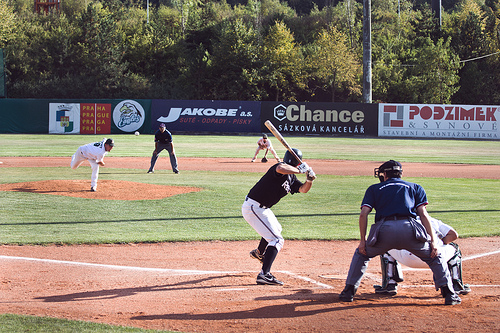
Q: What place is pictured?
A: It is a field.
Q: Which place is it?
A: It is a field.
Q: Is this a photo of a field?
A: Yes, it is showing a field.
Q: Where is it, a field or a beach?
A: It is a field.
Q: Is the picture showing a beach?
A: No, the picture is showing a field.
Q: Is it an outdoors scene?
A: Yes, it is outdoors.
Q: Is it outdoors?
A: Yes, it is outdoors.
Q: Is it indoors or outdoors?
A: It is outdoors.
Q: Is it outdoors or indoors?
A: It is outdoors.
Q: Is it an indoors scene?
A: No, it is outdoors.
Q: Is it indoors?
A: No, it is outdoors.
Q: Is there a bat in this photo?
A: Yes, there is a bat.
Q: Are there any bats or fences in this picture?
A: Yes, there is a bat.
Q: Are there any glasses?
A: No, there are no glasses.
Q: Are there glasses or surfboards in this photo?
A: No, there are no glasses or surfboards.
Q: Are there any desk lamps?
A: No, there are no desk lamps.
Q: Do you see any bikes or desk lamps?
A: No, there are no desk lamps or bikes.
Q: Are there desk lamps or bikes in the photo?
A: No, there are no desk lamps or bikes.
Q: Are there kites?
A: No, there are no kites.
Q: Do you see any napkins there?
A: No, there are no napkins.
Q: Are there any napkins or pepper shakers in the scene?
A: No, there are no napkins or pepper shakers.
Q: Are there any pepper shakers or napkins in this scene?
A: No, there are no napkins or pepper shakers.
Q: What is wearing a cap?
A: The pitcher is wearing a cap.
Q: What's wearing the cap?
A: The pitcher is wearing a cap.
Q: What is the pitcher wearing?
A: The pitcher is wearing a cap.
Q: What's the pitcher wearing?
A: The pitcher is wearing a cap.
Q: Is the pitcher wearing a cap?
A: Yes, the pitcher is wearing a cap.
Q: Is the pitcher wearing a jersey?
A: No, the pitcher is wearing a cap.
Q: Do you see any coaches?
A: No, there are no coaches.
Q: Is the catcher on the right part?
A: Yes, the catcher is on the right of the image.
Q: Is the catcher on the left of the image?
A: No, the catcher is on the right of the image.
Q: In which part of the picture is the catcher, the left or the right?
A: The catcher is on the right of the image.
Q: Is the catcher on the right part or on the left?
A: The catcher is on the right of the image.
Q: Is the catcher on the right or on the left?
A: The catcher is on the right of the image.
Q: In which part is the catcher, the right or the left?
A: The catcher is on the right of the image.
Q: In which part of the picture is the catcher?
A: The catcher is on the right of the image.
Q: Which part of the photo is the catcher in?
A: The catcher is on the right of the image.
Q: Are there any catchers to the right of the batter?
A: Yes, there is a catcher to the right of the batter.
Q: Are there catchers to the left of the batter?
A: No, the catcher is to the right of the batter.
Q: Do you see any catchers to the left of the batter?
A: No, the catcher is to the right of the batter.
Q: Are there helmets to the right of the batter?
A: No, there is a catcher to the right of the batter.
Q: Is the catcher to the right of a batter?
A: Yes, the catcher is to the right of a batter.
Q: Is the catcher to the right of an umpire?
A: No, the catcher is to the right of a batter.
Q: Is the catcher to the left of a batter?
A: No, the catcher is to the right of a batter.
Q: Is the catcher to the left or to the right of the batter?
A: The catcher is to the right of the batter.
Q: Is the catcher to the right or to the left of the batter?
A: The catcher is to the right of the batter.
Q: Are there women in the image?
A: No, there are no women.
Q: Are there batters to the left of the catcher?
A: Yes, there is a batter to the left of the catcher.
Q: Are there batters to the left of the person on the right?
A: Yes, there is a batter to the left of the catcher.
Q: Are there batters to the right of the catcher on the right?
A: No, the batter is to the left of the catcher.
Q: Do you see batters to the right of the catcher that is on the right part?
A: No, the batter is to the left of the catcher.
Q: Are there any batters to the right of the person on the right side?
A: No, the batter is to the left of the catcher.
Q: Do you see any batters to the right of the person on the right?
A: No, the batter is to the left of the catcher.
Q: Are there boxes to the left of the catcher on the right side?
A: No, there is a batter to the left of the catcher.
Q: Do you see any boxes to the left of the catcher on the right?
A: No, there is a batter to the left of the catcher.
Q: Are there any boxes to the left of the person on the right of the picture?
A: No, there is a batter to the left of the catcher.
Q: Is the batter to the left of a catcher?
A: Yes, the batter is to the left of a catcher.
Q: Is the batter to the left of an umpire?
A: No, the batter is to the left of a catcher.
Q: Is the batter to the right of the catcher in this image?
A: No, the batter is to the left of the catcher.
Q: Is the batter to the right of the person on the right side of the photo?
A: No, the batter is to the left of the catcher.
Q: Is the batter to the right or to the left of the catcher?
A: The batter is to the left of the catcher.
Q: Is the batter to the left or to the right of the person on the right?
A: The batter is to the left of the catcher.